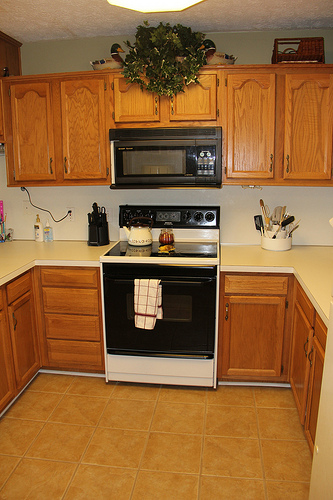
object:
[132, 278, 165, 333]
towel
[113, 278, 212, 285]
handle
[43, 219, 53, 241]
bottle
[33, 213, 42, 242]
bottle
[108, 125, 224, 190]
microwave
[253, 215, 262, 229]
utensils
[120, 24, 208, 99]
plant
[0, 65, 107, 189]
cabinet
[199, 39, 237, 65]
statue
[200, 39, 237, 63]
duck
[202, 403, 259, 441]
tile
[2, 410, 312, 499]
floor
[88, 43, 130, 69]
duck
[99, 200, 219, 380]
stove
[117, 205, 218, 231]
panel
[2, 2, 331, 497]
kitchen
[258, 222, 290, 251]
holder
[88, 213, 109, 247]
holder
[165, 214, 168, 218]
knobs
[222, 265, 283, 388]
cabinet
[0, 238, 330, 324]
counter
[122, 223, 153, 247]
tea pot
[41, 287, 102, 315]
drawers